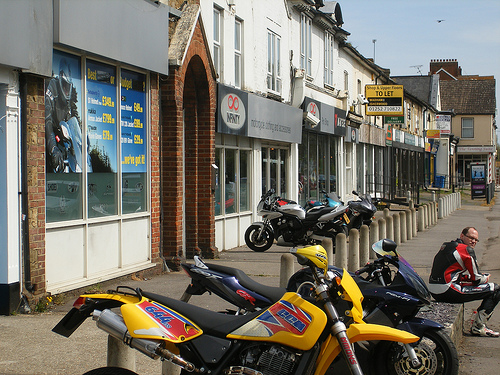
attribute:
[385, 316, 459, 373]
tire — black, motorcycle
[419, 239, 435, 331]
bike — blue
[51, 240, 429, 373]
bike — yellow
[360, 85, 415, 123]
sign — yellow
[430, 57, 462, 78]
brick chimney — wide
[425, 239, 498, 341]
outfit — white, black, red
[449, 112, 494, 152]
wall — brown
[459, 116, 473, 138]
window — two paned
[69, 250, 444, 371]
motorcycle — yellow, red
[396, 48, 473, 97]
roof — building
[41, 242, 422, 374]
motorbike — yellow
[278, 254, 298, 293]
barrier — cement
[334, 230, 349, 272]
barrier — cement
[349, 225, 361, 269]
barrier — cement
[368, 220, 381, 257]
barrier — cement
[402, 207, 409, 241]
barrier — cement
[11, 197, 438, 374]
sidewalk — cement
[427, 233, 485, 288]
shirt — red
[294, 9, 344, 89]
windows — tall, second story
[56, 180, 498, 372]
parking area — motorbike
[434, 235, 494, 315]
gear — colorful, leather, cycling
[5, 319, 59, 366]
floor — grey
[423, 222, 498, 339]
man — black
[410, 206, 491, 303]
man — sitting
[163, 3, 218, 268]
doorway — brick, circular, arched, pointed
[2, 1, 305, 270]
building — brick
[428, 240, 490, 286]
jacket — black and red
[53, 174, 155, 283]
doors — metallic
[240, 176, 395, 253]
motorbikes — parked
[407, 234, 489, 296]
man — seated 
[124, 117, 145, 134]
words — black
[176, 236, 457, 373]
motorcycle — black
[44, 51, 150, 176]
poster — advertising